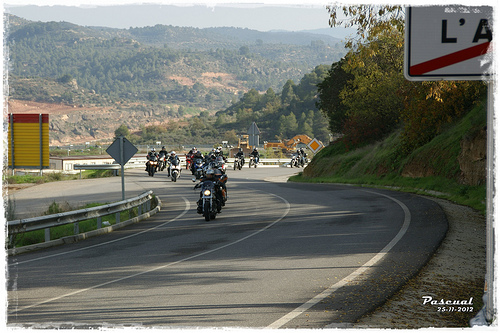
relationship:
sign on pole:
[401, 6, 491, 82] [487, 83, 497, 318]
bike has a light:
[192, 163, 228, 222] [202, 186, 213, 196]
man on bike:
[204, 153, 230, 193] [193, 163, 228, 220]